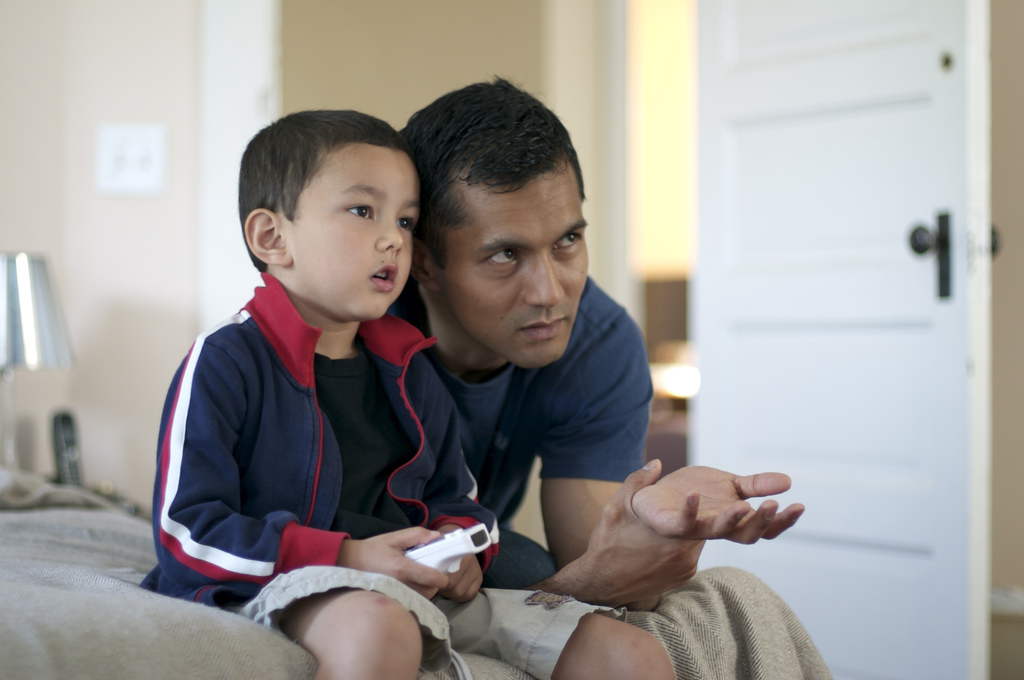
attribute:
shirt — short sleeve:
[452, 363, 634, 554]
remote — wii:
[401, 517, 499, 589]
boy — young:
[136, 104, 690, 679]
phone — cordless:
[43, 400, 98, 485]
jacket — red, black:
[133, 277, 522, 623]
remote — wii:
[399, 524, 505, 585]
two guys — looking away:
[143, 70, 805, 676]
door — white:
[694, 3, 990, 675]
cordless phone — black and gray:
[45, 400, 91, 500]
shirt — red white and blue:
[151, 277, 506, 625]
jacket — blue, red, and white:
[153, 271, 503, 596]